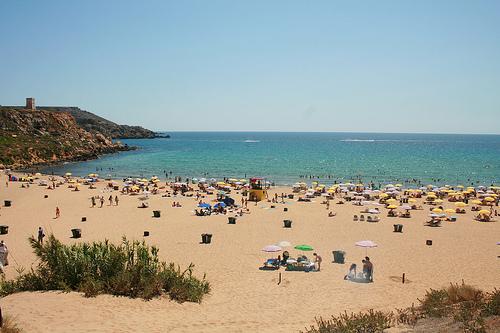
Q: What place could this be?
A: It is a beach.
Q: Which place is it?
A: It is a beach.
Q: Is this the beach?
A: Yes, it is the beach.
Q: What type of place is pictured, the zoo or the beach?
A: It is the beach.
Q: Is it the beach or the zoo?
A: It is the beach.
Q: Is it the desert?
A: No, it is the beach.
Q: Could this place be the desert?
A: No, it is the beach.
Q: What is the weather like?
A: It is clear.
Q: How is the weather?
A: It is clear.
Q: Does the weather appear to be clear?
A: Yes, it is clear.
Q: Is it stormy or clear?
A: It is clear.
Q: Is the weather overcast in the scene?
A: No, it is clear.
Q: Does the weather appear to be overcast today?
A: No, it is clear.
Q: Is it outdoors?
A: Yes, it is outdoors.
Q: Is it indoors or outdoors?
A: It is outdoors.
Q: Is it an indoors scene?
A: No, it is outdoors.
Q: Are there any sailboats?
A: No, there are no sailboats.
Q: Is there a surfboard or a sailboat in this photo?
A: No, there are no sailboats or surfboards.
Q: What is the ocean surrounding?
A: The ocean is surrounding the hill.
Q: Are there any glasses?
A: No, there are no glasses.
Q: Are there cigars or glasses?
A: No, there are no glasses or cigars.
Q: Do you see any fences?
A: No, there are no fences.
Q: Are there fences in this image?
A: No, there are no fences.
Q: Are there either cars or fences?
A: No, there are no fences or cars.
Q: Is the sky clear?
A: Yes, the sky is clear.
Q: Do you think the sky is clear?
A: Yes, the sky is clear.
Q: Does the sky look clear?
A: Yes, the sky is clear.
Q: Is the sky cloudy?
A: No, the sky is clear.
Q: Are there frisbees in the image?
A: No, there are no frisbees.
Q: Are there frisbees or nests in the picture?
A: No, there are no frisbees or nests.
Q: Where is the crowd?
A: The crowd is on the beach.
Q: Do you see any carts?
A: No, there are no carts.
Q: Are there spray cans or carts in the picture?
A: No, there are no carts or spray cans.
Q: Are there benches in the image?
A: No, there are no benches.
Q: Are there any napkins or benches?
A: No, there are no benches or napkins.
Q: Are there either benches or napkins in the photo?
A: No, there are no benches or napkins.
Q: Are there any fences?
A: No, there are no fences.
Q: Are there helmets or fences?
A: No, there are no fences or helmets.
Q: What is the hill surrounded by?
A: The hill is surrounded by the ocean.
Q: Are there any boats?
A: No, there are no boats.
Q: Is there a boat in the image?
A: No, there are no boats.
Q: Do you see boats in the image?
A: No, there are no boats.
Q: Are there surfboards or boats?
A: No, there are no boats or surfboards.